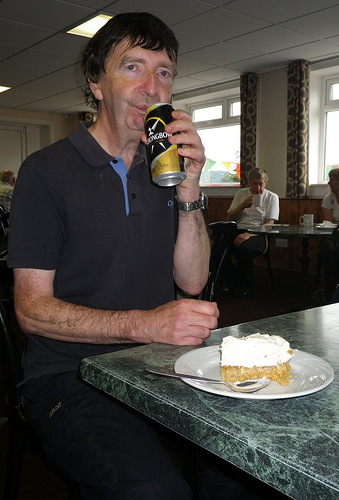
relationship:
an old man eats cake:
[0, 8, 240, 347] [216, 326, 296, 388]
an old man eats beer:
[0, 8, 240, 347] [138, 100, 187, 191]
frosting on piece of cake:
[215, 326, 293, 365] [204, 306, 298, 390]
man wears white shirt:
[221, 161, 283, 231] [221, 181, 294, 239]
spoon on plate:
[140, 359, 275, 399] [167, 336, 337, 405]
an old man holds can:
[8, 8, 241, 499] [138, 98, 189, 194]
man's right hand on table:
[14, 287, 221, 352] [68, 293, 337, 497]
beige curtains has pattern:
[234, 62, 333, 212] [284, 108, 308, 141]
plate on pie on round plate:
[167, 336, 337, 405] [176, 317, 324, 411]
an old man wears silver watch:
[8, 8, 241, 499] [162, 194, 215, 212]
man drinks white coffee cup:
[221, 161, 281, 248] [245, 191, 262, 210]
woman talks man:
[315, 164, 338, 225] [223, 167, 282, 228]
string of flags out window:
[200, 150, 246, 188] [168, 79, 249, 192]